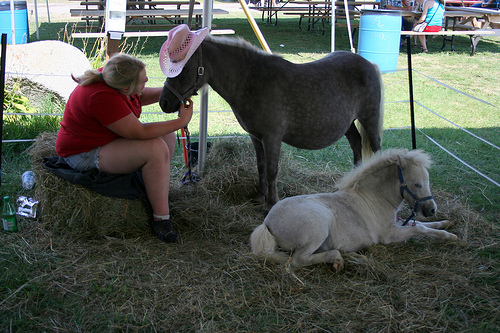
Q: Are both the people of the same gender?
A: Yes, all the people are female.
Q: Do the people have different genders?
A: No, all the people are female.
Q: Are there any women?
A: Yes, there is a woman.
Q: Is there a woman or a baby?
A: Yes, there is a woman.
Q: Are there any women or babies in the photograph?
A: Yes, there is a woman.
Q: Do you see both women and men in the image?
A: No, there is a woman but no men.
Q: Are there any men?
A: No, there are no men.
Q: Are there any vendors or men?
A: No, there are no men or vendors.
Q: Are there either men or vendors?
A: No, there are no men or vendors.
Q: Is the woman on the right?
A: Yes, the woman is on the right of the image.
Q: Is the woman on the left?
A: No, the woman is on the right of the image.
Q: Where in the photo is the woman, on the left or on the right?
A: The woman is on the right of the image.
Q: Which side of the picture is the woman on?
A: The woman is on the right of the image.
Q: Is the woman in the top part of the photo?
A: Yes, the woman is in the top of the image.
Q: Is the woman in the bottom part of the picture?
A: No, the woman is in the top of the image.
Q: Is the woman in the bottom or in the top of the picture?
A: The woman is in the top of the image.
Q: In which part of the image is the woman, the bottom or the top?
A: The woman is in the top of the image.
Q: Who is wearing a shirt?
A: The woman is wearing a shirt.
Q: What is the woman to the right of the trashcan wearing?
A: The woman is wearing a shirt.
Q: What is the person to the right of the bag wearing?
A: The woman is wearing a shirt.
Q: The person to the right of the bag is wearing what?
A: The woman is wearing a shirt.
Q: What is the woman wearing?
A: The woman is wearing a shirt.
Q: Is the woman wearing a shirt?
A: Yes, the woman is wearing a shirt.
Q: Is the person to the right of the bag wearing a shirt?
A: Yes, the woman is wearing a shirt.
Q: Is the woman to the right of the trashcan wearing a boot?
A: No, the woman is wearing a shirt.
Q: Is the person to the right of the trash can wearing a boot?
A: No, the woman is wearing a shirt.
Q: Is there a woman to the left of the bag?
A: No, the woman is to the right of the bag.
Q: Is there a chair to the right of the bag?
A: No, there is a woman to the right of the bag.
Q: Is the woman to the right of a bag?
A: Yes, the woman is to the right of a bag.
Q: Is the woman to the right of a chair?
A: No, the woman is to the right of a bag.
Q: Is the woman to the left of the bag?
A: No, the woman is to the right of the bag.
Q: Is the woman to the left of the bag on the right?
A: No, the woman is to the right of the bag.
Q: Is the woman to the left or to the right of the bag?
A: The woman is to the right of the bag.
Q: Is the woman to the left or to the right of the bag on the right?
A: The woman is to the right of the bag.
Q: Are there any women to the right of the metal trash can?
A: Yes, there is a woman to the right of the garbage can.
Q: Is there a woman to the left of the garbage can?
A: No, the woman is to the right of the garbage can.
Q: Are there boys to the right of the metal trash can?
A: No, there is a woman to the right of the garbage bin.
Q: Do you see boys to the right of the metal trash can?
A: No, there is a woman to the right of the garbage bin.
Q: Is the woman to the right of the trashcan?
A: Yes, the woman is to the right of the trashcan.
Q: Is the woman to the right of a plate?
A: No, the woman is to the right of the trashcan.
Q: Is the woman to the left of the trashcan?
A: No, the woman is to the right of the trashcan.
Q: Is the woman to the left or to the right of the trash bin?
A: The woman is to the right of the trash bin.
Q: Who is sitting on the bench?
A: The woman is sitting on the bench.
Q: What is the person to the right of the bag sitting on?
A: The woman is sitting on the bench.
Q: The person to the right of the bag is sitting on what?
A: The woman is sitting on the bench.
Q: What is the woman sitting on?
A: The woman is sitting on the bench.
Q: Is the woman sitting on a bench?
A: Yes, the woman is sitting on a bench.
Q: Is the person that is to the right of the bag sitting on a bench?
A: Yes, the woman is sitting on a bench.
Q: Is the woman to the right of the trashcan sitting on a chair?
A: No, the woman is sitting on a bench.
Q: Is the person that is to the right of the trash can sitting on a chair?
A: No, the woman is sitting on a bench.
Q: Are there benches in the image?
A: Yes, there is a bench.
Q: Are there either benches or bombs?
A: Yes, there is a bench.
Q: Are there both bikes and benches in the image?
A: No, there is a bench but no bikes.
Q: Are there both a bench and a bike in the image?
A: No, there is a bench but no bikes.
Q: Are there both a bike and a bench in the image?
A: No, there is a bench but no bikes.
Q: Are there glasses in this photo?
A: No, there are no glasses.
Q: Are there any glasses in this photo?
A: No, there are no glasses.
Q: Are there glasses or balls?
A: No, there are no glasses or balls.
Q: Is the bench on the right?
A: Yes, the bench is on the right of the image.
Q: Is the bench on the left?
A: No, the bench is on the right of the image.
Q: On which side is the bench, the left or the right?
A: The bench is on the right of the image.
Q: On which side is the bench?
A: The bench is on the right of the image.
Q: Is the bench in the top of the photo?
A: Yes, the bench is in the top of the image.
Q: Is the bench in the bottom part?
A: No, the bench is in the top of the image.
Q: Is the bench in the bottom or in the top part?
A: The bench is in the top of the image.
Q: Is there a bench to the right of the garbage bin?
A: Yes, there is a bench to the right of the garbage bin.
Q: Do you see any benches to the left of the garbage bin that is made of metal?
A: No, the bench is to the right of the garbage bin.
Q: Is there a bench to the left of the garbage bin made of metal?
A: No, the bench is to the right of the garbage bin.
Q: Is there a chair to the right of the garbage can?
A: No, there is a bench to the right of the garbage can.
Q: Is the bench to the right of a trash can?
A: Yes, the bench is to the right of a trash can.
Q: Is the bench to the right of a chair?
A: No, the bench is to the right of a trash can.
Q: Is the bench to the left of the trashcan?
A: No, the bench is to the right of the trashcan.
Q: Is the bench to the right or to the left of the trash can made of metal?
A: The bench is to the right of the garbage bin.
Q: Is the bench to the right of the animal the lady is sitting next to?
A: Yes, the bench is to the right of the animal.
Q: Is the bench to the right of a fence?
A: No, the bench is to the right of the animal.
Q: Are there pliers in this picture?
A: No, there are no pliers.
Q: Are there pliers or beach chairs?
A: No, there are no pliers or beach chairs.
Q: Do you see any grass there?
A: Yes, there is grass.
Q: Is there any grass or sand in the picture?
A: Yes, there is grass.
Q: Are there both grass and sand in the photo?
A: No, there is grass but no sand.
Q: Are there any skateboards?
A: No, there are no skateboards.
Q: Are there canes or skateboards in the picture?
A: No, there are no skateboards or canes.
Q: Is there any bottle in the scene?
A: Yes, there is a bottle.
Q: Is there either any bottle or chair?
A: Yes, there is a bottle.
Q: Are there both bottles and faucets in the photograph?
A: No, there is a bottle but no faucets.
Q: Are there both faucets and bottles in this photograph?
A: No, there is a bottle but no faucets.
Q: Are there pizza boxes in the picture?
A: No, there are no pizza boxes.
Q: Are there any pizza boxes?
A: No, there are no pizza boxes.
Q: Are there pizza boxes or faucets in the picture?
A: No, there are no pizza boxes or faucets.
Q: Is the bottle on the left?
A: Yes, the bottle is on the left of the image.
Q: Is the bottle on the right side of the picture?
A: No, the bottle is on the left of the image.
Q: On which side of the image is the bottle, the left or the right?
A: The bottle is on the left of the image.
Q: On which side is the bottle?
A: The bottle is on the left of the image.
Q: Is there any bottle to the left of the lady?
A: Yes, there is a bottle to the left of the lady.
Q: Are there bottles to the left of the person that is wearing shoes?
A: Yes, there is a bottle to the left of the lady.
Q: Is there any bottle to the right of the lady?
A: No, the bottle is to the left of the lady.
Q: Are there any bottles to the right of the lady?
A: No, the bottle is to the left of the lady.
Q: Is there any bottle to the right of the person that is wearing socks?
A: No, the bottle is to the left of the lady.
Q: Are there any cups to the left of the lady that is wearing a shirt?
A: No, there is a bottle to the left of the lady.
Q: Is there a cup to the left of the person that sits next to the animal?
A: No, there is a bottle to the left of the lady.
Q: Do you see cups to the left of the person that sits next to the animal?
A: No, there is a bottle to the left of the lady.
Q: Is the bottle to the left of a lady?
A: Yes, the bottle is to the left of a lady.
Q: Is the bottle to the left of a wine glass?
A: No, the bottle is to the left of a lady.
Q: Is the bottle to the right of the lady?
A: No, the bottle is to the left of the lady.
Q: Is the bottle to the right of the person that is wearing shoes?
A: No, the bottle is to the left of the lady.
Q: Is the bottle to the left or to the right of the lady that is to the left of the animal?
A: The bottle is to the left of the lady.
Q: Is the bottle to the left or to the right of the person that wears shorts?
A: The bottle is to the left of the lady.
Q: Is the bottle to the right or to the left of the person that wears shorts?
A: The bottle is to the left of the lady.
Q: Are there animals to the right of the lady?
A: Yes, there is an animal to the right of the lady.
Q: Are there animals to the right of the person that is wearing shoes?
A: Yes, there is an animal to the right of the lady.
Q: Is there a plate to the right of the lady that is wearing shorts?
A: No, there is an animal to the right of the lady.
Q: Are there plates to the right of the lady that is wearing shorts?
A: No, there is an animal to the right of the lady.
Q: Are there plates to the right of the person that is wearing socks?
A: No, there is an animal to the right of the lady.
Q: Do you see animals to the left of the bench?
A: Yes, there is an animal to the left of the bench.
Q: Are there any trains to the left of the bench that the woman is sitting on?
A: No, there is an animal to the left of the bench.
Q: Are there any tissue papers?
A: No, there are no tissue papers.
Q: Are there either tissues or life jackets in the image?
A: No, there are no tissues or life jackets.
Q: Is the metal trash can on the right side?
A: Yes, the trash can is on the right of the image.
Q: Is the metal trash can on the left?
A: No, the trash can is on the right of the image.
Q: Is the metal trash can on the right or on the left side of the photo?
A: The trash can is on the right of the image.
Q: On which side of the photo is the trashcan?
A: The trashcan is on the right of the image.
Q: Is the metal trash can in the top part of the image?
A: Yes, the garbage can is in the top of the image.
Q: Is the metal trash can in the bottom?
A: No, the trash can is in the top of the image.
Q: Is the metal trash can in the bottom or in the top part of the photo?
A: The trashcan is in the top of the image.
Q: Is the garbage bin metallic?
A: Yes, the garbage bin is metallic.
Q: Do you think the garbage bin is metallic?
A: Yes, the garbage bin is metallic.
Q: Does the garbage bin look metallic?
A: Yes, the garbage bin is metallic.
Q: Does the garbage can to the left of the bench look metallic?
A: Yes, the trashcan is metallic.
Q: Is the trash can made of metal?
A: Yes, the trash can is made of metal.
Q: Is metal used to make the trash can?
A: Yes, the trash can is made of metal.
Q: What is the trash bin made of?
A: The trash bin is made of metal.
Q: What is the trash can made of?
A: The trash bin is made of metal.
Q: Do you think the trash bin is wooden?
A: No, the trash bin is metallic.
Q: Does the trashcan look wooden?
A: No, the trashcan is metallic.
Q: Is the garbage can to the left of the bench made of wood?
A: No, the garbage bin is made of metal.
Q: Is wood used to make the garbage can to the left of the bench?
A: No, the garbage bin is made of metal.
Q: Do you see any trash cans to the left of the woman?
A: Yes, there is a trash can to the left of the woman.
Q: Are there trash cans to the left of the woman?
A: Yes, there is a trash can to the left of the woman.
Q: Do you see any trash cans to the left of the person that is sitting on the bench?
A: Yes, there is a trash can to the left of the woman.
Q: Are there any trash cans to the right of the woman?
A: No, the trash can is to the left of the woman.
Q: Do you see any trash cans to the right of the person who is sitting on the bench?
A: No, the trash can is to the left of the woman.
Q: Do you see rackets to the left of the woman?
A: No, there is a trash can to the left of the woman.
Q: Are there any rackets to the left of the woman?
A: No, there is a trash can to the left of the woman.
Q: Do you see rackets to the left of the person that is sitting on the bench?
A: No, there is a trash can to the left of the woman.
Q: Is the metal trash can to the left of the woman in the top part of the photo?
A: Yes, the trash bin is to the left of the woman.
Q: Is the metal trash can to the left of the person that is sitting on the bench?
A: Yes, the trash bin is to the left of the woman.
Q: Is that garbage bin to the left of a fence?
A: No, the garbage bin is to the left of the woman.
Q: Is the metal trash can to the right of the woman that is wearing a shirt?
A: No, the garbage can is to the left of the woman.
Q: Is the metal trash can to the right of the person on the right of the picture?
A: No, the garbage can is to the left of the woman.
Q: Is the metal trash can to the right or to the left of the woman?
A: The garbage can is to the left of the woman.